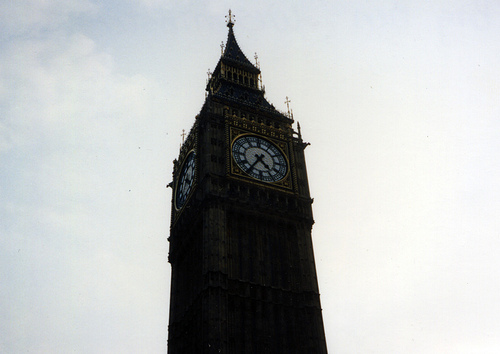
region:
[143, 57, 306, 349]
tall clock tower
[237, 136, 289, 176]
white face on tower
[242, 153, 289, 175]
black hands on tower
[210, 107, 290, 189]
gold border around tower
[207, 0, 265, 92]
tall spire on tower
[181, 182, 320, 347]
brown exterior of clock tower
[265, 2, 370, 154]
blue and white sky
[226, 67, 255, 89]
arched windows near top of tower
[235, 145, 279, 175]
clock hands read 4:36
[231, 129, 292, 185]
a blue and white clock with a yellow rim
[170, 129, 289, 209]
two clocks on the sides of the tower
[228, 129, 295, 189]
a round clock at the top of a tower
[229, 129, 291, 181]
round clock with Roman numerals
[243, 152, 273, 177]
hands on the clock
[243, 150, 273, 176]
hands indicating the time is 4:35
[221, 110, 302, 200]
gold square decoration around the edges of the clock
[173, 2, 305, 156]
successively smaller roofs above the clock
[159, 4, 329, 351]
an old, imposing tower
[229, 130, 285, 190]
this is a clock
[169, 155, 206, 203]
this is a clock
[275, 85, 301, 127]
a cross sign on top of the tower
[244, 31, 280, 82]
a cross sign on top of the tower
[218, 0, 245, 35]
a cross sign on top of the tower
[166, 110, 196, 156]
a cross sign on top of the tower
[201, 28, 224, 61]
a cross sign on top of the tower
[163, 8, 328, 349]
A clock tower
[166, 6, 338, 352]
A dark clock tower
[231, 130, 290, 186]
A blue and white clock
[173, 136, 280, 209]
Two clocks on a tower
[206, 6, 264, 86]
The top of a clock tower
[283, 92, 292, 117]
Cross on a clock tower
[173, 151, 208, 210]
A clock on a clock tower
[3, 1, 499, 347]
Sunny and light background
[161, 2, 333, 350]
A tall building outdoors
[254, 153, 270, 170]
The hand of a clock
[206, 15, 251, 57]
spire on the tower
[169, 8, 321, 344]
the tall clock tower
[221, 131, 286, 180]
clock on the tower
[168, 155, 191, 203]
clock on the side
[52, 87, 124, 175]
clouds in the sky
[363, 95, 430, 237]
the sky is hazy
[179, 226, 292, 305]
the tower is dark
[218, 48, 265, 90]
roof of the tower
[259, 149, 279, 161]
pattern on the clock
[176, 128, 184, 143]
spire on the clock tower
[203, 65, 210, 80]
spire on the clock tower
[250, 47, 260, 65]
spire on the clock tower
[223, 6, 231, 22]
spire on the clock tower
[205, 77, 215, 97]
spire on the clock tower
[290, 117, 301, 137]
spire on the clock tower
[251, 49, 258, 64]
spire on the clock tower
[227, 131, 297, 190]
a clock on the tower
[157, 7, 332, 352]
a large tower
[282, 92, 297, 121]
a cross on the right side of the tower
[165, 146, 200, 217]
a clock on the left side of the tower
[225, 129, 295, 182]
a round clock on the tower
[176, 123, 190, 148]
a cross on the left side of the tower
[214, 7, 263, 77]
a cone shaped roof on the tower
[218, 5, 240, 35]
a spiral on top of the tower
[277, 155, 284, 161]
A number on a clock.